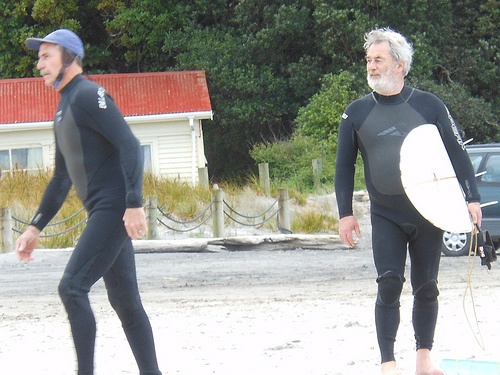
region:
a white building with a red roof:
[4, 47, 241, 220]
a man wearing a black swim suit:
[337, 21, 491, 373]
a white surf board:
[368, 100, 475, 260]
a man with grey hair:
[323, 19, 483, 249]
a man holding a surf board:
[344, 18, 490, 259]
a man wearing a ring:
[13, 18, 163, 256]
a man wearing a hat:
[13, 25, 165, 240]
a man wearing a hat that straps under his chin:
[16, 25, 149, 232]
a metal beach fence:
[0, 188, 342, 272]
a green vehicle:
[418, 122, 498, 250]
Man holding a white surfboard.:
[332, 27, 481, 373]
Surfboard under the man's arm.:
[397, 123, 483, 230]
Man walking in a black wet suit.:
[14, 30, 164, 373]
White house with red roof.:
[0, 70, 213, 200]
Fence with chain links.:
[0, 157, 323, 252]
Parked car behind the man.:
[437, 141, 498, 255]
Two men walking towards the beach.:
[17, 19, 480, 374]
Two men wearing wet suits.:
[14, 4, 483, 373]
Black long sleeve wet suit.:
[29, 74, 160, 374]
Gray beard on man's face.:
[365, 72, 397, 94]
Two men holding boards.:
[14, 12, 448, 367]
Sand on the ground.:
[193, 198, 350, 367]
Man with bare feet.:
[357, 316, 476, 371]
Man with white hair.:
[323, 36, 463, 163]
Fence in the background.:
[174, 152, 309, 267]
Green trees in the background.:
[187, 31, 337, 207]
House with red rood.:
[9, 60, 240, 140]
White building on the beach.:
[3, 46, 398, 326]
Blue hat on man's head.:
[30, 28, 128, 129]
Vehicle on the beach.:
[395, 111, 495, 224]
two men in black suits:
[48, 8, 451, 365]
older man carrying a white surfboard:
[358, 10, 488, 362]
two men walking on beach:
[53, 8, 471, 361]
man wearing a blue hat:
[16, 21, 93, 101]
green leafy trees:
[223, 16, 322, 151]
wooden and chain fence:
[162, 180, 293, 241]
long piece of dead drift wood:
[133, 231, 363, 261]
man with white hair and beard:
[331, 11, 442, 111]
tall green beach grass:
[135, 176, 227, 233]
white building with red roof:
[0, 56, 213, 218]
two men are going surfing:
[5, 31, 467, 340]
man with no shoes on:
[334, 292, 463, 370]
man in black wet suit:
[320, 75, 441, 340]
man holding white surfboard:
[383, 113, 461, 275]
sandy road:
[180, 253, 337, 368]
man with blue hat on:
[15, 11, 153, 291]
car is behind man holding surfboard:
[420, 110, 493, 276]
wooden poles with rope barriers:
[147, 170, 299, 251]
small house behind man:
[2, 50, 213, 241]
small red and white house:
[133, 69, 221, 234]